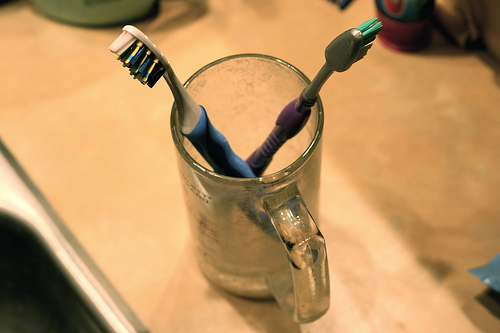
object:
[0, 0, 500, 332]
table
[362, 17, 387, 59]
toothpaste top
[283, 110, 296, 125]
rubber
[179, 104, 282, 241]
rubber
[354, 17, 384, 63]
bristles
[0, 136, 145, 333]
counteredge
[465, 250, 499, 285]
paper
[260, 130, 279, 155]
purple stripe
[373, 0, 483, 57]
bottle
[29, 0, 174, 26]
green object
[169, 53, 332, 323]
cup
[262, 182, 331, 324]
handle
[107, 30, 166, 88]
bristles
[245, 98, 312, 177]
handle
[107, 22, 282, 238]
blue toothbrush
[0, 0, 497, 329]
background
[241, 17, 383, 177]
tooth brush